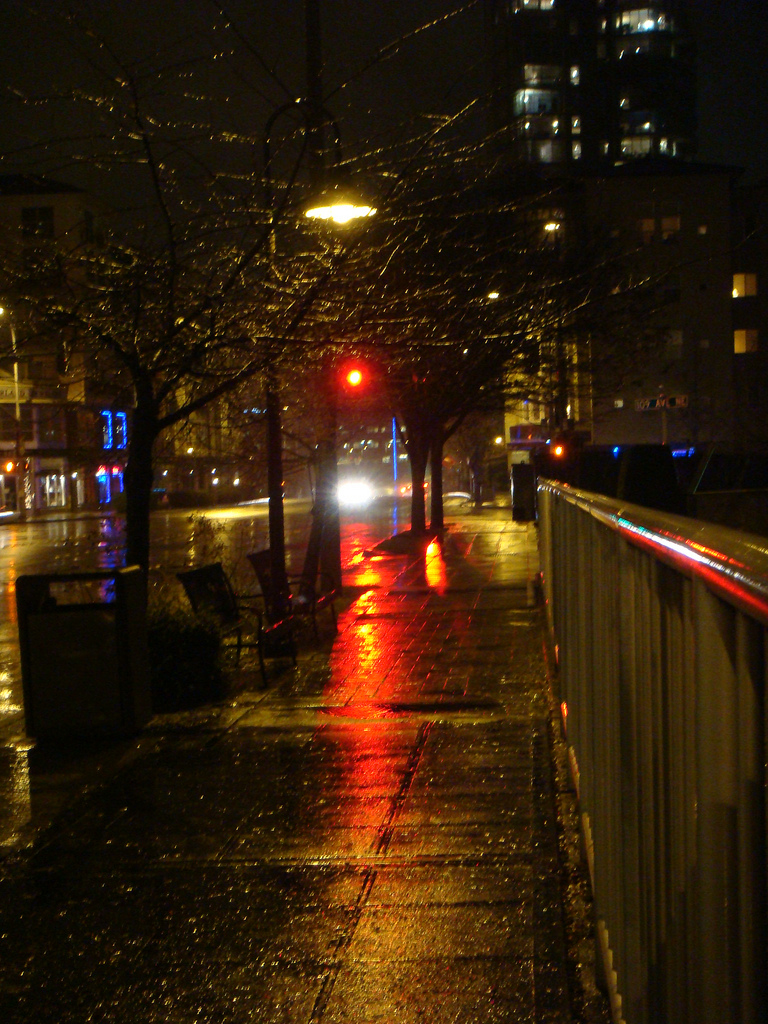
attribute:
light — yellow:
[298, 198, 379, 226]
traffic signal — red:
[326, 350, 372, 396]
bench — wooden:
[247, 546, 343, 634]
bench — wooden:
[176, 557, 296, 670]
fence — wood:
[528, 476, 766, 1021]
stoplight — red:
[345, 366, 362, 386]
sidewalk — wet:
[0, 487, 617, 1020]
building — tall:
[357, 0, 766, 535]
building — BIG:
[342, 0, 766, 492]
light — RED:
[345, 366, 360, 386]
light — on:
[292, 177, 388, 237]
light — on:
[522, 208, 568, 238]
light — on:
[523, 431, 571, 465]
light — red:
[329, 347, 372, 394]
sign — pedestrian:
[0, 446, 50, 486]